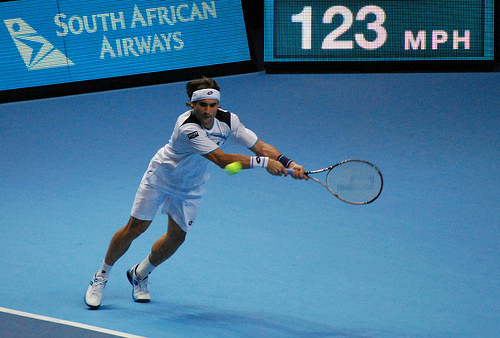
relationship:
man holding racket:
[86, 77, 309, 307] [284, 159, 383, 206]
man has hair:
[86, 77, 309, 307] [184, 76, 219, 105]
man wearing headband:
[86, 77, 309, 307] [191, 88, 222, 101]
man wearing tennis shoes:
[86, 77, 309, 307] [125, 265, 151, 303]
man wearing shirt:
[86, 77, 309, 307] [140, 109, 257, 204]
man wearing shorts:
[86, 77, 309, 307] [129, 184, 200, 232]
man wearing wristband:
[86, 77, 309, 307] [278, 154, 292, 172]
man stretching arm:
[86, 77, 309, 307] [182, 128, 271, 172]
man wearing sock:
[86, 77, 309, 307] [137, 258, 156, 278]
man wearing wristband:
[86, 77, 309, 307] [251, 155, 269, 168]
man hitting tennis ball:
[86, 77, 309, 307] [226, 161, 242, 174]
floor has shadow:
[1, 68, 499, 335] [98, 301, 356, 337]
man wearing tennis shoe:
[86, 77, 309, 307] [84, 274, 107, 310]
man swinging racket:
[86, 77, 309, 307] [284, 159, 383, 206]